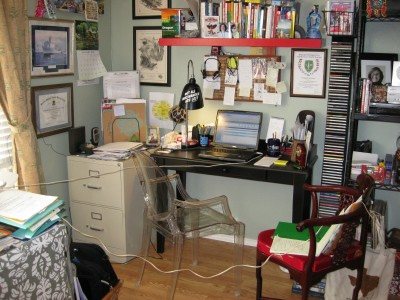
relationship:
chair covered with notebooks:
[254, 173, 367, 298] [273, 222, 331, 257]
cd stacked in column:
[330, 90, 348, 105] [314, 6, 360, 226]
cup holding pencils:
[267, 137, 281, 157] [270, 131, 278, 140]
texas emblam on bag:
[351, 268, 377, 296] [324, 199, 397, 300]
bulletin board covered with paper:
[204, 56, 282, 105] [235, 59, 254, 87]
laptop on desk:
[209, 108, 258, 162] [153, 131, 310, 263]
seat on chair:
[258, 224, 362, 268] [254, 173, 367, 298]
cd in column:
[330, 90, 348, 105] [314, 6, 360, 226]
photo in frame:
[150, 129, 156, 141] [145, 122, 162, 152]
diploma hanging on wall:
[30, 87, 75, 130] [19, 3, 129, 202]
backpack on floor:
[67, 240, 120, 298] [96, 233, 328, 300]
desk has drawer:
[153, 131, 310, 263] [184, 158, 267, 182]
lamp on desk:
[180, 59, 204, 149] [153, 131, 310, 263]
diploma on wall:
[30, 87, 75, 130] [19, 3, 129, 202]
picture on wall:
[23, 18, 80, 77] [19, 3, 129, 202]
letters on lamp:
[181, 90, 198, 103] [180, 59, 204, 149]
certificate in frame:
[296, 56, 322, 92] [287, 47, 325, 100]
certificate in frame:
[296, 56, 322, 92] [145, 122, 162, 152]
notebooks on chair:
[273, 222, 331, 257] [254, 173, 367, 298]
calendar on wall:
[74, 18, 108, 86] [19, 3, 129, 202]